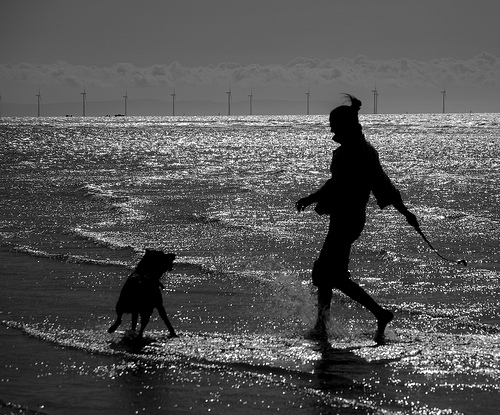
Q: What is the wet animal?
A: Dog.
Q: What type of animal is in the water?
A: Dog.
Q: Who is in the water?
A: Woman and dog.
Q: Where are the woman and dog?
A: The beach.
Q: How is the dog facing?
A: The woman.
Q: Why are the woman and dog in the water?
A: Playing.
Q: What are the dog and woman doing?
A: Playing.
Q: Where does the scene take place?
A: At the beach.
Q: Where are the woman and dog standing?
A: On the beach.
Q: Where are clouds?
A: In the sky.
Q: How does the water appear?
A: Calm.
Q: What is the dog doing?
A: Playing.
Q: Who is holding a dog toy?
A: The woman.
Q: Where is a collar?
A: Around dog's neck.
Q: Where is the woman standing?
A: In the water.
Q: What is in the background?
A: Light poles.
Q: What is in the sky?
A: Line of clouds.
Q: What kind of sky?
A: Gray night.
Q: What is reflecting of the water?
A: Light.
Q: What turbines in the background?
A: The wind.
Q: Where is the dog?
A: The beach.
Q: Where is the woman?
A: The beach.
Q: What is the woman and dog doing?
A: Playing.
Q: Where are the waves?
A: On the water.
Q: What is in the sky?
A: Clouds.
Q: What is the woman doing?
A: Playing with the dog.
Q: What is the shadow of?
A: The woman.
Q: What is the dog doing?
A: Playing with the man.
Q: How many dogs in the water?
A: One.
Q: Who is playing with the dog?
A: The man.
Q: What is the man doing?
A: Holding a stick.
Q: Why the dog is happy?
A: He is playing.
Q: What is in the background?
A: Windmills.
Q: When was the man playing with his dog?
A: Just now.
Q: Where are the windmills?
A: On the other side of the beach.